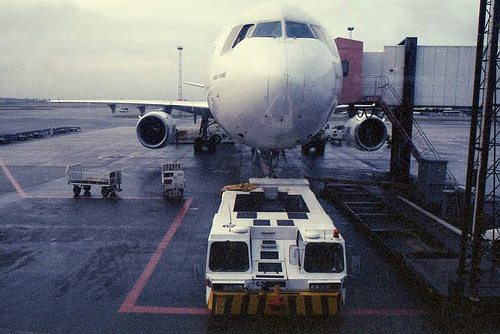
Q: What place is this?
A: It is a pavement.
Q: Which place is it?
A: It is a pavement.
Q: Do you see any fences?
A: No, there are no fences.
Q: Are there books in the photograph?
A: No, there are no books.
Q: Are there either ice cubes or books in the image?
A: No, there are no books or ice cubes.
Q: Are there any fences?
A: No, there are no fences.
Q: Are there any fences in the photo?
A: No, there are no fences.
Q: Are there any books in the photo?
A: No, there are no books.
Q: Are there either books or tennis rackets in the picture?
A: No, there are no books or tennis rackets.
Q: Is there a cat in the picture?
A: No, there are no cats.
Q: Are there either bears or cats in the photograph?
A: No, there are no cats or bears.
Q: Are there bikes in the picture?
A: No, there are no bikes.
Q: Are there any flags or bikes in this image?
A: No, there are no bikes or flags.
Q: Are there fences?
A: No, there are no fences.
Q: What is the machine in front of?
A: The machine is in front of the airport.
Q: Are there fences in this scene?
A: No, there are no fences.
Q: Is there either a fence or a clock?
A: No, there are no fences or clocks.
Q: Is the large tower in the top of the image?
A: Yes, the tower is in the top of the image.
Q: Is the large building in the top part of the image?
A: Yes, the tower is in the top of the image.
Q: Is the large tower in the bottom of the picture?
A: No, the tower is in the top of the image.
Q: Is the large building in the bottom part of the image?
A: No, the tower is in the top of the image.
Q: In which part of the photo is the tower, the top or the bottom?
A: The tower is in the top of the image.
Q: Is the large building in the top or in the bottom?
A: The tower is in the top of the image.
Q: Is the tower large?
A: Yes, the tower is large.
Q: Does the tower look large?
A: Yes, the tower is large.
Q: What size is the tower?
A: The tower is large.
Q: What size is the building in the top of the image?
A: The tower is large.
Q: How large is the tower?
A: The tower is large.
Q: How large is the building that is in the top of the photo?
A: The tower is large.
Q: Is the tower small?
A: No, the tower is large.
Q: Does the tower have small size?
A: No, the tower is large.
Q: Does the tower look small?
A: No, the tower is large.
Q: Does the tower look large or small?
A: The tower is large.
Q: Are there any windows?
A: Yes, there is a window.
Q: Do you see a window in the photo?
A: Yes, there is a window.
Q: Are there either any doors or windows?
A: Yes, there is a window.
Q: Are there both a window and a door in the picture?
A: No, there is a window but no doors.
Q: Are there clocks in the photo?
A: No, there are no clocks.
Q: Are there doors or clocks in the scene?
A: No, there are no clocks or doors.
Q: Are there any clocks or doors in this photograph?
A: No, there are no clocks or doors.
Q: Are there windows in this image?
A: Yes, there is a window.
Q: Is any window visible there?
A: Yes, there is a window.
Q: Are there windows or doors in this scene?
A: Yes, there is a window.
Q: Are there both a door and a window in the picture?
A: No, there is a window but no doors.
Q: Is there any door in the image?
A: No, there are no doors.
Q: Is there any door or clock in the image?
A: No, there are no doors or clocks.